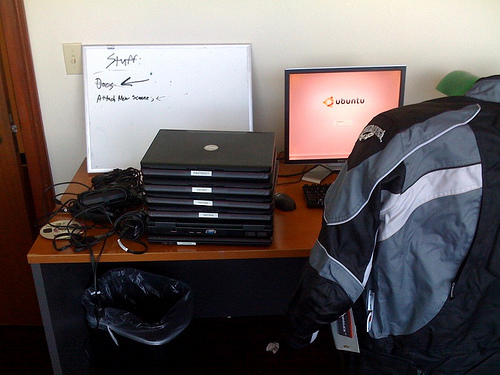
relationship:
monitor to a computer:
[282, 66, 409, 165] [330, 309, 362, 359]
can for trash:
[81, 266, 196, 372] [261, 336, 282, 359]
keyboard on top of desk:
[304, 182, 330, 210] [26, 157, 341, 272]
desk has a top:
[26, 157, 341, 272] [26, 157, 341, 272]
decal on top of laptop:
[203, 143, 220, 152] [138, 163, 274, 184]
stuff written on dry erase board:
[105, 52, 141, 72] [84, 44, 253, 174]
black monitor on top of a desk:
[282, 66, 409, 165] [26, 157, 341, 272]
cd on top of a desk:
[39, 218, 84, 239] [26, 157, 341, 272]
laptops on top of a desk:
[141, 127, 279, 246] [26, 157, 341, 272]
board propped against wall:
[84, 44, 253, 174] [270, 3, 499, 65]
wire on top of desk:
[53, 218, 110, 268] [26, 157, 341, 272]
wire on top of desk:
[93, 167, 137, 186] [26, 157, 341, 272]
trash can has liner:
[81, 266, 196, 372] [79, 266, 197, 333]